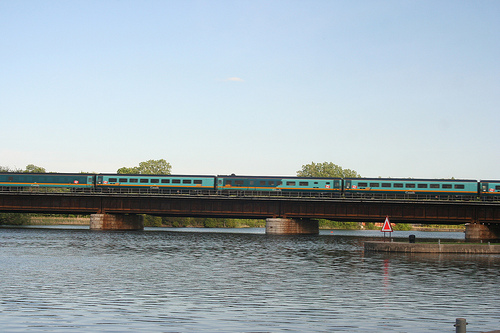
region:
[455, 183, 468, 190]
window on passenger train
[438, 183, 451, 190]
window on passenger train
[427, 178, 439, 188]
window on passenger train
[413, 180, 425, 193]
window on passenger train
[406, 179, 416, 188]
window on passenger train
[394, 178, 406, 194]
window on passenger train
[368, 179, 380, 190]
window on passenger train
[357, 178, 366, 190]
window on passenger train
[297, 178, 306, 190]
window on passenger train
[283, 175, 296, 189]
window on passenger train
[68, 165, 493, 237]
green train on bridge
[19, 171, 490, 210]
grey rail on bridge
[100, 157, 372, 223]
green trees behind bridge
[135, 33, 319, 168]
blue and white sky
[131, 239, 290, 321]
water has small ripples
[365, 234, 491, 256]
brown pier near water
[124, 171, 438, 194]
rectangular windows on train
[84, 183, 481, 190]
orange stripe on train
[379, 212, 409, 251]
red and white sign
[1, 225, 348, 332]
large body of water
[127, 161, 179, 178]
trees beside the train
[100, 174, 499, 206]
train moving on train tracks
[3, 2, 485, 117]
blue sky during the day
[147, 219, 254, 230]
green bushes beside train track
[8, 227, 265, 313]
calm waters in the river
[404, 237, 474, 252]
grass beside the train tracks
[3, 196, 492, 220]
bridge with train on it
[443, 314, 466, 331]
silver pole near the water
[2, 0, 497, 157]
blue sky over a moving train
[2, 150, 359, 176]
tops of trees showing above a train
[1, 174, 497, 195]
blue, black and red train on a track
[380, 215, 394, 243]
triangular black, white and red sign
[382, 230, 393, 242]
two posts holding up a sign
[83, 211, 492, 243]
brick style pylons holding a train bridge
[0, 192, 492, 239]
bridge with a train track and train on it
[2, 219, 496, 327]
wide river under a train bridge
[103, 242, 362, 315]
ripples in the river water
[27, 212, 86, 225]
grassy area near the bridge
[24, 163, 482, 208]
green train on bridge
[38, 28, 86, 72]
white clouds in blue sky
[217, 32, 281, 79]
white clouds in blue sky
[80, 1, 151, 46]
white clouds in blue sky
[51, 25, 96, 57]
white clouds in blue sky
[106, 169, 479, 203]
a train on the bridge.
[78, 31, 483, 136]
The sky is clear and blue.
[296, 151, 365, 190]
Tree behind the train.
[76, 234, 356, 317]
The water is calm and dark.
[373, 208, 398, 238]
Warning sign on side of bridge.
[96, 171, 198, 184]
Windows on the train.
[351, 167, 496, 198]
The train is green.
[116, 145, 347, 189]
The trees are green.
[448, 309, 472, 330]
Pole in the water.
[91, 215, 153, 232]
platform of the bridge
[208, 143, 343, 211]
A green and blue train car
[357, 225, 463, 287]
A concrete walkway that leads into the water